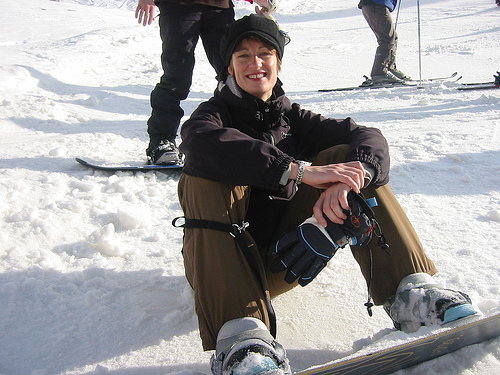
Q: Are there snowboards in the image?
A: Yes, there is a snowboard.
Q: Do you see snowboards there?
A: Yes, there is a snowboard.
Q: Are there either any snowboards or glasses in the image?
A: Yes, there is a snowboard.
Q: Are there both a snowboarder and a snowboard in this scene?
A: Yes, there are both a snowboard and a snowboarder.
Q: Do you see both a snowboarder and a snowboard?
A: Yes, there are both a snowboard and a snowboarder.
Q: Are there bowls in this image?
A: No, there are no bowls.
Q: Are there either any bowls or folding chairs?
A: No, there are no bowls or folding chairs.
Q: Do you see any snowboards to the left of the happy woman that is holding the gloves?
A: Yes, there is a snowboard to the left of the woman.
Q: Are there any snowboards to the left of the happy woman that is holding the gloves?
A: Yes, there is a snowboard to the left of the woman.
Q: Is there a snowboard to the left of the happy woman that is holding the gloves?
A: Yes, there is a snowboard to the left of the woman.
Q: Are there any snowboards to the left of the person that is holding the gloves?
A: Yes, there is a snowboard to the left of the woman.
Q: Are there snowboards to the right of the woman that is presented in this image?
A: No, the snowboard is to the left of the woman.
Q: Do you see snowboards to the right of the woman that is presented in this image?
A: No, the snowboard is to the left of the woman.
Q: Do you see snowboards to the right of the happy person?
A: No, the snowboard is to the left of the woman.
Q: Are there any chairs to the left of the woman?
A: No, there is a snowboard to the left of the woman.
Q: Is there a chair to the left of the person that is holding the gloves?
A: No, there is a snowboard to the left of the woman.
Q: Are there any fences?
A: No, there are no fences.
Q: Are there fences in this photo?
A: No, there are no fences.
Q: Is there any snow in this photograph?
A: Yes, there is snow.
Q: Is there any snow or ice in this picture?
A: Yes, there is snow.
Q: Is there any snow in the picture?
A: Yes, there is snow.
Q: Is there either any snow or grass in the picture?
A: Yes, there is snow.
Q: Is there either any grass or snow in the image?
A: Yes, there is snow.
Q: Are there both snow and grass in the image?
A: No, there is snow but no grass.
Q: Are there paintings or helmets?
A: No, there are no helmets or paintings.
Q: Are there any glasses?
A: No, there are no glasses.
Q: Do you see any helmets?
A: No, there are no helmets.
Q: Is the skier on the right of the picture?
A: Yes, the skier is on the right of the image.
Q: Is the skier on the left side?
A: No, the skier is on the right of the image.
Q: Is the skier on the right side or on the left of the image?
A: The skier is on the right of the image.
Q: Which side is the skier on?
A: The skier is on the right of the image.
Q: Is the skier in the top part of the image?
A: Yes, the skier is in the top of the image.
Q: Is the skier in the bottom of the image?
A: No, the skier is in the top of the image.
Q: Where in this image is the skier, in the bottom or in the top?
A: The skier is in the top of the image.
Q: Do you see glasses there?
A: No, there are no glasses.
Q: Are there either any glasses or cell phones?
A: No, there are no glasses or cell phones.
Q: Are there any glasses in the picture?
A: No, there are no glasses.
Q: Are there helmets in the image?
A: No, there are no helmets.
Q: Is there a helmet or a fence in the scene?
A: No, there are no helmets or fences.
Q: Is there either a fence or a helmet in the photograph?
A: No, there are no helmets or fences.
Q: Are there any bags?
A: No, there are no bags.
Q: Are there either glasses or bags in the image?
A: No, there are no bags or glasses.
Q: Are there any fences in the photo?
A: No, there are no fences.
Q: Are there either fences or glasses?
A: No, there are no fences or glasses.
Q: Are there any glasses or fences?
A: No, there are no fences or glasses.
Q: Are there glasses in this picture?
A: No, there are no glasses.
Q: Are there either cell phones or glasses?
A: No, there are no glasses or cell phones.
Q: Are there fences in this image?
A: No, there are no fences.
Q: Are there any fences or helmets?
A: No, there are no fences or helmets.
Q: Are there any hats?
A: Yes, there is a hat.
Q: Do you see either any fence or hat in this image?
A: Yes, there is a hat.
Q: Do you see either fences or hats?
A: Yes, there is a hat.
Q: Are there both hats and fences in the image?
A: No, there is a hat but no fences.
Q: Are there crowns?
A: No, there are no crowns.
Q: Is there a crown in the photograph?
A: No, there are no crowns.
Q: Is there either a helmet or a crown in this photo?
A: No, there are no crowns or helmets.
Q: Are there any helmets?
A: No, there are no helmets.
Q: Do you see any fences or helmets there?
A: No, there are no helmets or fences.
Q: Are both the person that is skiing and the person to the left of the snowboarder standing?
A: Yes, both the person and the person are standing.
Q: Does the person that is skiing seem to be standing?
A: Yes, the person is standing.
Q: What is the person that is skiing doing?
A: The person is standing.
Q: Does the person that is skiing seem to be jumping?
A: No, the person is standing.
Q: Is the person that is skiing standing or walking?
A: The person is standing.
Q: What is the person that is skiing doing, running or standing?
A: The person is standing.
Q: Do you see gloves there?
A: Yes, there are gloves.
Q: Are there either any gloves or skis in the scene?
A: Yes, there are gloves.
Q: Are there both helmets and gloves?
A: No, there are gloves but no helmets.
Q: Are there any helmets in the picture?
A: No, there are no helmets.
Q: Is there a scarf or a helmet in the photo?
A: No, there are no helmets or scarves.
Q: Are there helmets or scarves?
A: No, there are no helmets or scarves.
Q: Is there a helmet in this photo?
A: No, there are no helmets.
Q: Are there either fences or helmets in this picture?
A: No, there are no helmets or fences.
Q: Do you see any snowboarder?
A: Yes, there is a snowboarder.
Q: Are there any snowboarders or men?
A: Yes, there is a snowboarder.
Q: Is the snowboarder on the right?
A: Yes, the snowboarder is on the right of the image.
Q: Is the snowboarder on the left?
A: No, the snowboarder is on the right of the image.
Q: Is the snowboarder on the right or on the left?
A: The snowboarder is on the right of the image.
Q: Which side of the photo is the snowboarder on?
A: The snowboarder is on the right of the image.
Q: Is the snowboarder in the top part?
A: Yes, the snowboarder is in the top of the image.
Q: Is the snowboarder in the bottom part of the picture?
A: No, the snowboarder is in the top of the image.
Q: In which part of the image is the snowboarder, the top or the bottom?
A: The snowboarder is in the top of the image.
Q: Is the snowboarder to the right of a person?
A: Yes, the snowboarder is to the right of a person.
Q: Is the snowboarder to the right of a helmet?
A: No, the snowboarder is to the right of a person.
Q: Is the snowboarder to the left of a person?
A: No, the snowboarder is to the right of a person.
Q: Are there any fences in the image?
A: No, there are no fences.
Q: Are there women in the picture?
A: Yes, there is a woman.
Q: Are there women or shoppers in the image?
A: Yes, there is a woman.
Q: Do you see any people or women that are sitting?
A: Yes, the woman is sitting.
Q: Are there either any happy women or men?
A: Yes, there is a happy woman.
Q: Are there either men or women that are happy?
A: Yes, the woman is happy.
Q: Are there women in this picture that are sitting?
A: Yes, there is a woman that is sitting.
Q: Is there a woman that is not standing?
A: Yes, there is a woman that is sitting.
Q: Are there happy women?
A: Yes, there is a happy woman.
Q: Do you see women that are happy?
A: Yes, there is a woman that is happy.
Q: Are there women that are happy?
A: Yes, there is a woman that is happy.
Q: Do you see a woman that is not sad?
A: Yes, there is a happy woman.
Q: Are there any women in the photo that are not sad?
A: Yes, there is a happy woman.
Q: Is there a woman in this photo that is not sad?
A: Yes, there is a happy woman.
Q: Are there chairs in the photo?
A: No, there are no chairs.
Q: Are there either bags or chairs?
A: No, there are no chairs or bags.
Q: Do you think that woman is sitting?
A: Yes, the woman is sitting.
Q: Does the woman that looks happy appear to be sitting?
A: Yes, the woman is sitting.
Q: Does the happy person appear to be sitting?
A: Yes, the woman is sitting.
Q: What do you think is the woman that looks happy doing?
A: The woman is sitting.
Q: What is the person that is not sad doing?
A: The woman is sitting.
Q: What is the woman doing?
A: The woman is sitting.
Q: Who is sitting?
A: The woman is sitting.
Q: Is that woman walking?
A: No, the woman is sitting.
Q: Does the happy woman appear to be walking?
A: No, the woman is sitting.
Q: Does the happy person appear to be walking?
A: No, the woman is sitting.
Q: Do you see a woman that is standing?
A: No, there is a woman but she is sitting.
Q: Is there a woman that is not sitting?
A: No, there is a woman but she is sitting.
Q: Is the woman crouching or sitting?
A: The woman is sitting.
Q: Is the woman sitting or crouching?
A: The woman is sitting.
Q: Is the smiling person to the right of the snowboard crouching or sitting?
A: The woman is sitting.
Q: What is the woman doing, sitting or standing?
A: The woman is sitting.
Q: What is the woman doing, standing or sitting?
A: The woman is sitting.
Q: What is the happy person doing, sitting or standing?
A: The woman is sitting.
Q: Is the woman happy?
A: Yes, the woman is happy.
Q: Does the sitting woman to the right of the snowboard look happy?
A: Yes, the woman is happy.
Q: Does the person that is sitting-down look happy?
A: Yes, the woman is happy.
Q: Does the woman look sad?
A: No, the woman is happy.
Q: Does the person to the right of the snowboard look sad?
A: No, the woman is happy.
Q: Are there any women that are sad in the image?
A: No, there is a woman but she is happy.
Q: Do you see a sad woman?
A: No, there is a woman but she is happy.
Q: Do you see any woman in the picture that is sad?
A: No, there is a woman but she is happy.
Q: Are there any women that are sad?
A: No, there is a woman but she is happy.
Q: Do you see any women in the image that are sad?
A: No, there is a woman but she is happy.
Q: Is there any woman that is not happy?
A: No, there is a woman but she is happy.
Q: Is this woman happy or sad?
A: The woman is happy.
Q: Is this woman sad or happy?
A: The woman is happy.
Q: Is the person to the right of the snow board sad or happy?
A: The woman is happy.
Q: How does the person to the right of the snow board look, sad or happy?
A: The woman is happy.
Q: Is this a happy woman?
A: Yes, this is a happy woman.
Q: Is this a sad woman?
A: No, this is a happy woman.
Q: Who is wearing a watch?
A: The woman is wearing a watch.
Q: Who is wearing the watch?
A: The woman is wearing a watch.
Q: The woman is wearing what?
A: The woman is wearing a watch.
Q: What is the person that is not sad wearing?
A: The woman is wearing a watch.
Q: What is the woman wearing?
A: The woman is wearing a watch.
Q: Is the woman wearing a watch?
A: Yes, the woman is wearing a watch.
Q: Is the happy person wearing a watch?
A: Yes, the woman is wearing a watch.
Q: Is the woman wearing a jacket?
A: No, the woman is wearing a watch.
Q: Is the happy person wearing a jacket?
A: No, the woman is wearing a watch.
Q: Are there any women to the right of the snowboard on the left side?
A: Yes, there is a woman to the right of the snowboard.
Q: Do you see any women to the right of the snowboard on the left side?
A: Yes, there is a woman to the right of the snowboard.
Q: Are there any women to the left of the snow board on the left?
A: No, the woman is to the right of the snowboard.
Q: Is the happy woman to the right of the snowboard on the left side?
A: Yes, the woman is to the right of the snowboard.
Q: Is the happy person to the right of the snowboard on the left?
A: Yes, the woman is to the right of the snowboard.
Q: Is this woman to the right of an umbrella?
A: No, the woman is to the right of the snowboard.